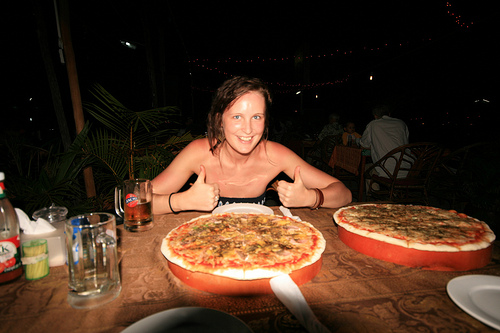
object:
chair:
[359, 141, 429, 205]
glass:
[114, 178, 154, 233]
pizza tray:
[336, 226, 491, 272]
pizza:
[333, 203, 494, 252]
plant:
[74, 82, 191, 201]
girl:
[135, 75, 352, 215]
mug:
[60, 211, 122, 309]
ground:
[485, 215, 493, 221]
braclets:
[309, 188, 325, 211]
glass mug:
[112, 176, 154, 232]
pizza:
[160, 211, 326, 280]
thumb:
[196, 165, 205, 184]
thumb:
[294, 165, 302, 181]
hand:
[183, 164, 220, 212]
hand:
[276, 165, 309, 208]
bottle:
[0, 172, 24, 286]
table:
[1, 204, 499, 331]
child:
[342, 122, 362, 147]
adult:
[347, 102, 419, 200]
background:
[0, 0, 484, 76]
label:
[0, 235, 21, 272]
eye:
[251, 114, 262, 120]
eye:
[233, 115, 243, 120]